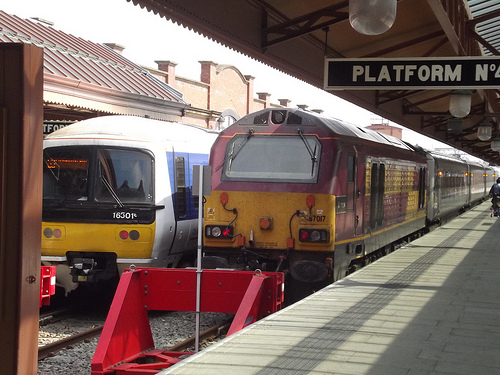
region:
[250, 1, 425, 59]
light fixture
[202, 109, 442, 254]
red and yellow train car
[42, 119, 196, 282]
end of train car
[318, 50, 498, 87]
sign which tells platform number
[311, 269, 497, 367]
part of concrete walkway in train station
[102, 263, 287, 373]
red triangular shaped blockade on train track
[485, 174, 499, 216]
part of the back of a person showing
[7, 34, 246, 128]
part of roof to train station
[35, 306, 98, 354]
part of train track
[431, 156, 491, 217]
train cars gray in appearance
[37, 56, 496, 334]
two trains on the track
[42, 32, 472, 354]
two trains next to each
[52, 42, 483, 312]
two trains next to each other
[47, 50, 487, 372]
trains next to a plateform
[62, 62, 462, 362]
trains next to a platform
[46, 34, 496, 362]
passenger trains sitting still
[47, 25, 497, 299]
passenger trains parked at platform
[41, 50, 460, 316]
passenger trains next to each other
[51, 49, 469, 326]
passenger trains during the day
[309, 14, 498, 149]
platform sign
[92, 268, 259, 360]
a metal red train stopper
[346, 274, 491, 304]
a shadow on the platform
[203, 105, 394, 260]
a burgundy and yellow train car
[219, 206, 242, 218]
a black cord on the train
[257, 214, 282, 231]
a round orange light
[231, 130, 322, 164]
windshield on the train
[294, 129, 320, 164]
a black windshield on the train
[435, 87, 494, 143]
white tubular lights overhead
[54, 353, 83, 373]
gray gravel between the tracks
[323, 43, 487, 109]
a black and white sign on the platform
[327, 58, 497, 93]
the sign hangs above the platform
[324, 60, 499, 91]
the sign says platform No 4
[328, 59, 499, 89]
the sign is black and white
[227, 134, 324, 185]
the window on the engine of the train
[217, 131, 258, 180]
windshield wipers are on the window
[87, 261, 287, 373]
a red barracade sits on the track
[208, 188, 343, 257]
the bottom front of the engine is yellow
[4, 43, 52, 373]
a wooden beam at the side of the platform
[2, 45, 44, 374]
the beam is brown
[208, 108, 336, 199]
the top part of the engine is silver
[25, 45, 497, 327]
two trains on the platform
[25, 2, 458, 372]
two trains at the platform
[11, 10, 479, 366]
two trains on tracks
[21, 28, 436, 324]
two passenger trains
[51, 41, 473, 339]
two passenger trains parked at station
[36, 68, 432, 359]
two passenger trains on trakcs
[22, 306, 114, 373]
rocks underneath the track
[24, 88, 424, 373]
train tracks with two passenger trains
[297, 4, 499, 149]
platform sign hanging